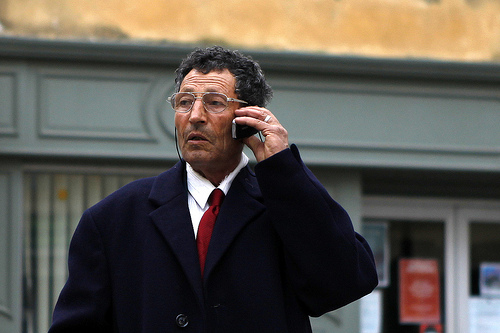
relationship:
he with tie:
[47, 44, 381, 332] [196, 185, 226, 275]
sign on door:
[394, 249, 451, 329] [363, 215, 458, 331]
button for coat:
[175, 313, 187, 328] [46, 142, 377, 332]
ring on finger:
[264, 115, 272, 123] [226, 112, 280, 137]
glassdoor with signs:
[447, 220, 492, 262] [400, 254, 492, 311]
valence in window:
[20, 173, 138, 332] [32, 170, 54, 331]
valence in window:
[20, 173, 186, 331] [31, 173, 176, 315]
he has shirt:
[35, 49, 385, 331] [165, 145, 276, 275]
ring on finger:
[264, 115, 272, 123] [234, 108, 277, 127]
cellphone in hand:
[210, 105, 272, 160] [222, 98, 305, 166]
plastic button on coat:
[175, 311, 190, 328] [31, 147, 390, 331]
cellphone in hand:
[231, 116, 260, 139] [225, 105, 305, 163]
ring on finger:
[261, 109, 280, 129] [235, 107, 281, 131]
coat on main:
[46, 142, 377, 332] [50, 45, 377, 332]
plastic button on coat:
[175, 311, 191, 328] [46, 142, 377, 332]